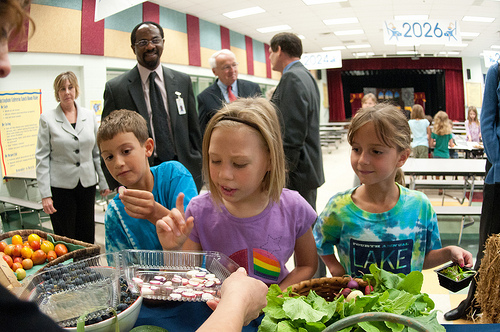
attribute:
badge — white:
[173, 90, 186, 114]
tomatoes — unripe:
[2, 229, 77, 284]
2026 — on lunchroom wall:
[390, 10, 455, 55]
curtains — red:
[323, 55, 465, 126]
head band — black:
[209, 113, 263, 134]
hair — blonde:
[347, 104, 418, 141]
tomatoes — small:
[2, 232, 67, 278]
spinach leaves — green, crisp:
[367, 270, 431, 310]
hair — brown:
[97, 117, 197, 147]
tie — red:
[215, 80, 244, 110]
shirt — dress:
[30, 104, 110, 196]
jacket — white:
[30, 102, 112, 199]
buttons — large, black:
[74, 134, 77, 142]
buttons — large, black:
[70, 146, 82, 155]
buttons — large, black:
[74, 159, 84, 168]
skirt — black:
[44, 180, 101, 246]